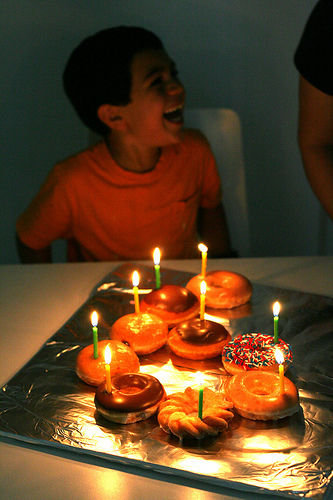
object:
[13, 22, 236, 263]
child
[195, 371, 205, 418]
candle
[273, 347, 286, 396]
candle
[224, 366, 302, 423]
doughnut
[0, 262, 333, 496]
foil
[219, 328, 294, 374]
doughnut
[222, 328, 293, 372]
sprinkles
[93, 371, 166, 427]
doughnut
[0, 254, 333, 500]
table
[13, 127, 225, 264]
t-shirt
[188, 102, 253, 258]
chair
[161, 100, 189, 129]
mouth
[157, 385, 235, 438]
cruller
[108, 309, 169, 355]
doughnut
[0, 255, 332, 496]
pan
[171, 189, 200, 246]
pocket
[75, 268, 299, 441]
number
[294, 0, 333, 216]
arm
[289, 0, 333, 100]
shirt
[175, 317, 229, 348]
chocolate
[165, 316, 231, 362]
doughnut